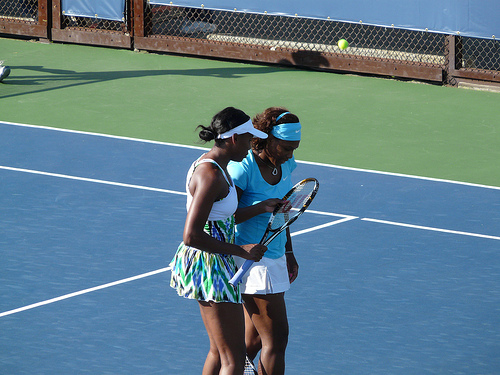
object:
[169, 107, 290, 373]
tennis player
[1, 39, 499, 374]
court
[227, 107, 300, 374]
tennis player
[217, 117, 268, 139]
visor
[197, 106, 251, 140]
hair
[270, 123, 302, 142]
band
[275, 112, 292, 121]
band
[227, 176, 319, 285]
racket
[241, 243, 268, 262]
hand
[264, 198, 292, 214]
hand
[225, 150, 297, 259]
shirt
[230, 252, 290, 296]
skirt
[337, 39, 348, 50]
ball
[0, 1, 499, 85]
fence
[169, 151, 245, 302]
tennis dress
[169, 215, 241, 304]
designs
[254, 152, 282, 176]
necklace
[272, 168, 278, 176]
pendant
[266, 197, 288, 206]
fingers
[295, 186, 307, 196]
strings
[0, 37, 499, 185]
out-of-bounds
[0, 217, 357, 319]
singles line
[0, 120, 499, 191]
line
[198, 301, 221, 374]
leg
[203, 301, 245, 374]
leg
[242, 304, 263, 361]
leg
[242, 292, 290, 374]
leg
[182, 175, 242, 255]
arm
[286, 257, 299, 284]
hand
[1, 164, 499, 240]
line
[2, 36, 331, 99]
shadow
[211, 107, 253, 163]
head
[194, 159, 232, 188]
strap